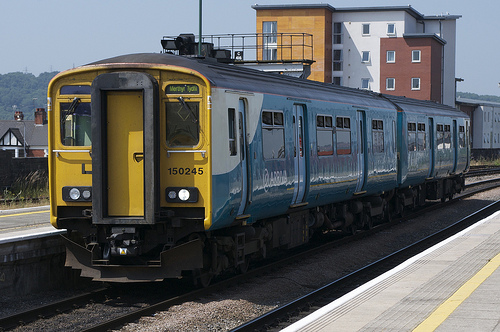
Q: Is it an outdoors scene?
A: Yes, it is outdoors.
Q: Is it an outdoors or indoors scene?
A: It is outdoors.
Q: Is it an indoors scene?
A: No, it is outdoors.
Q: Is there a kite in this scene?
A: No, there are no kites.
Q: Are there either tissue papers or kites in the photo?
A: No, there are no kites or tissue papers.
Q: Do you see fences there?
A: No, there are no fences.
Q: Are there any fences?
A: No, there are no fences.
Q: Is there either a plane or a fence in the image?
A: No, there are no fences or airplanes.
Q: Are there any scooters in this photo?
A: No, there are no scooters.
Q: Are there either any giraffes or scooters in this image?
A: No, there are no scooters or giraffes.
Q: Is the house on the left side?
A: Yes, the house is on the left of the image.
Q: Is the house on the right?
A: No, the house is on the left of the image.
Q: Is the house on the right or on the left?
A: The house is on the left of the image.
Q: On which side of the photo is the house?
A: The house is on the left of the image.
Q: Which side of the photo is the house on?
A: The house is on the left of the image.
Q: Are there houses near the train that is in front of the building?
A: Yes, there is a house near the train.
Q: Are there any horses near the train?
A: No, there is a house near the train.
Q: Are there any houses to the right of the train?
A: No, the house is to the left of the train.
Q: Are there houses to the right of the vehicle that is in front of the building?
A: No, the house is to the left of the train.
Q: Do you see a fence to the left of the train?
A: No, there is a house to the left of the train.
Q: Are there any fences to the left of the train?
A: No, there is a house to the left of the train.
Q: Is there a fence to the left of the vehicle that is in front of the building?
A: No, there is a house to the left of the train.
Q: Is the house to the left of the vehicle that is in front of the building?
A: Yes, the house is to the left of the train.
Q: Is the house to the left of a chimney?
A: No, the house is to the left of the train.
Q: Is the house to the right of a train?
A: No, the house is to the left of a train.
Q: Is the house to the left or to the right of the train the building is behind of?
A: The house is to the left of the train.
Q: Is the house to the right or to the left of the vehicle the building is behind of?
A: The house is to the left of the train.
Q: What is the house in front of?
A: The house is in front of the hill.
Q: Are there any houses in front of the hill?
A: Yes, there is a house in front of the hill.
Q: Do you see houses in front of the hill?
A: Yes, there is a house in front of the hill.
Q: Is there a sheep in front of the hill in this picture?
A: No, there is a house in front of the hill.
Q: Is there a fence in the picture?
A: No, there are no fences.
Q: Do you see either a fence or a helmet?
A: No, there are no fences or helmets.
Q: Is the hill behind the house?
A: Yes, the hill is behind the house.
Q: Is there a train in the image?
A: Yes, there is a train.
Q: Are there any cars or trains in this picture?
A: Yes, there is a train.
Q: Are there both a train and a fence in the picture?
A: No, there is a train but no fences.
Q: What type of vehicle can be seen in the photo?
A: The vehicle is a train.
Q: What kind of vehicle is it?
A: The vehicle is a train.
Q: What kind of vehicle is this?
A: This is a train.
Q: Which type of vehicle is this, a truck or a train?
A: This is a train.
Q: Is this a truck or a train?
A: This is a train.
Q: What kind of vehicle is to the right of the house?
A: The vehicle is a train.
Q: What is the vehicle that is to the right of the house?
A: The vehicle is a train.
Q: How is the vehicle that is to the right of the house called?
A: The vehicle is a train.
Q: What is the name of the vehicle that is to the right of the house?
A: The vehicle is a train.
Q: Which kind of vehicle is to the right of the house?
A: The vehicle is a train.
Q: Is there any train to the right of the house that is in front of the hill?
A: Yes, there is a train to the right of the house.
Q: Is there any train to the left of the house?
A: No, the train is to the right of the house.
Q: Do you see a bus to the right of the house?
A: No, there is a train to the right of the house.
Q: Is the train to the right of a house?
A: Yes, the train is to the right of a house.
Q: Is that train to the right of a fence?
A: No, the train is to the right of a house.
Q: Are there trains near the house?
A: Yes, there is a train near the house.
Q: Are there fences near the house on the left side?
A: No, there is a train near the house.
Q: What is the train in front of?
A: The train is in front of the building.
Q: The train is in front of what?
A: The train is in front of the building.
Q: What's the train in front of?
A: The train is in front of the building.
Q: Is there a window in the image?
A: Yes, there is a window.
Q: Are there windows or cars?
A: Yes, there is a window.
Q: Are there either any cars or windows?
A: Yes, there is a window.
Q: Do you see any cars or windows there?
A: Yes, there is a window.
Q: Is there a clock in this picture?
A: No, there are no clocks.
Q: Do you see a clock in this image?
A: No, there are no clocks.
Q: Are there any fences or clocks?
A: No, there are no clocks or fences.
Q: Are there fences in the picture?
A: No, there are no fences.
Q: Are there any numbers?
A: Yes, there are numbers.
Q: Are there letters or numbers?
A: Yes, there are numbers.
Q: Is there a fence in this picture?
A: No, there are no fences.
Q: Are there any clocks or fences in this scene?
A: No, there are no fences or clocks.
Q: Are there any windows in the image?
A: Yes, there are windows.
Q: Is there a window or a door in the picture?
A: Yes, there are windows.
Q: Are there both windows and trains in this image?
A: Yes, there are both windows and a train.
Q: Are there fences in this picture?
A: No, there are no fences.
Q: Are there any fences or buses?
A: No, there are no fences or buses.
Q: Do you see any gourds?
A: No, there are no gourds.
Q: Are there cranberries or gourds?
A: No, there are no gourds or cranberries.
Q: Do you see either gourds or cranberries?
A: No, there are no gourds or cranberries.